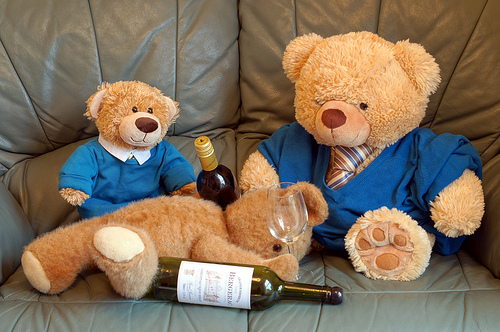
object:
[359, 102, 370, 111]
eye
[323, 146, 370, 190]
tie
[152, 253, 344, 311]
bottle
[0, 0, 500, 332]
couch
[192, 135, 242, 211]
bottle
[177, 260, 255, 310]
white surfboard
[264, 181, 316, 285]
glass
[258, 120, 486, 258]
shirt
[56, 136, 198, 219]
shirt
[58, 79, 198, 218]
bear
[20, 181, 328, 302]
bear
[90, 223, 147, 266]
paw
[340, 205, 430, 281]
paw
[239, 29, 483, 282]
bear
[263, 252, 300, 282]
hand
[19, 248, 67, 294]
paw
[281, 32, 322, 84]
ear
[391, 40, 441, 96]
ear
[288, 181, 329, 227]
ear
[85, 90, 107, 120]
ear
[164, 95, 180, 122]
ear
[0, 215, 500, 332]
cushion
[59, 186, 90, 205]
hand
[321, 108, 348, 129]
nose